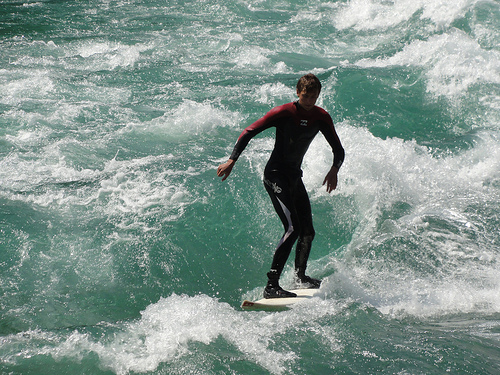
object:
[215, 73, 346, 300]
man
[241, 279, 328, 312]
surfboard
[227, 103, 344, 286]
wetsuit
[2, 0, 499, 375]
water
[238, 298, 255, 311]
tip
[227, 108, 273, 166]
arm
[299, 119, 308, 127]
logo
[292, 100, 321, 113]
neck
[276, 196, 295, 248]
white stripe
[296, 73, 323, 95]
hair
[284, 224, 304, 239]
knees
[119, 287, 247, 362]
wave